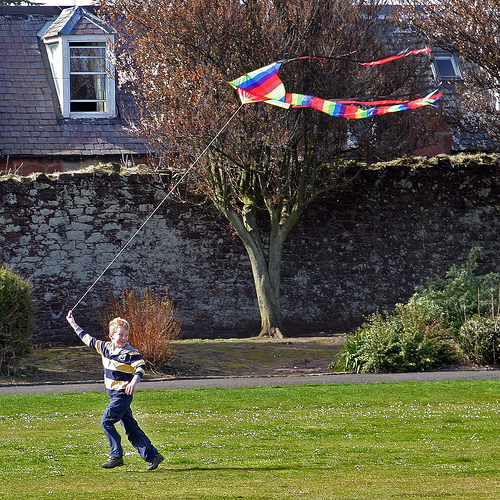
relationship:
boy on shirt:
[64, 310, 164, 472] [92, 348, 132, 395]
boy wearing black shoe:
[64, 310, 164, 474] [100, 455, 124, 467]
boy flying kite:
[64, 310, 164, 474] [197, 30, 459, 145]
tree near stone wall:
[92, 0, 432, 342] [0, 151, 499, 340]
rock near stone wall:
[68, 189, 92, 210] [0, 151, 499, 340]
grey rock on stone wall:
[67, 227, 87, 243] [0, 151, 499, 340]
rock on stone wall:
[50, 215, 72, 224] [0, 151, 499, 340]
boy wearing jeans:
[64, 310, 164, 472] [100, 390, 158, 462]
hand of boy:
[61, 301, 76, 320] [58, 310, 156, 478]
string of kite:
[68, 102, 246, 317] [217, 45, 452, 119]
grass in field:
[3, 389, 499, 499] [2, 341, 499, 498]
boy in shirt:
[64, 310, 164, 474] [74, 321, 147, 396]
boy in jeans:
[64, 310, 164, 474] [99, 393, 159, 460]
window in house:
[64, 30, 112, 116] [0, 0, 498, 175]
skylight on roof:
[431, 52, 462, 79] [0, 4, 497, 161]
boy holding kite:
[64, 310, 164, 472] [246, 45, 428, 110]